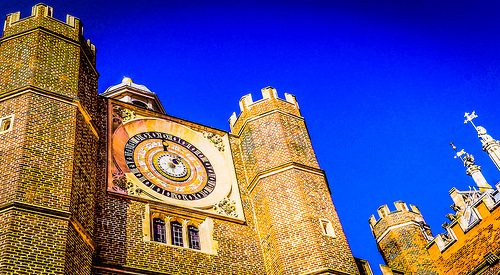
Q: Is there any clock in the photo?
A: Yes, there is a clock.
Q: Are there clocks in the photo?
A: Yes, there is a clock.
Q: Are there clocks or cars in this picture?
A: Yes, there is a clock.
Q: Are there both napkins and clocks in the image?
A: No, there is a clock but no napkins.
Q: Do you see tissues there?
A: No, there are no tissues.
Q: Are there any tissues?
A: No, there are no tissues.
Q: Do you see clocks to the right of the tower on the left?
A: Yes, there is a clock to the right of the tower.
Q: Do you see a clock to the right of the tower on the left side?
A: Yes, there is a clock to the right of the tower.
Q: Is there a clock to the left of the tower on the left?
A: No, the clock is to the right of the tower.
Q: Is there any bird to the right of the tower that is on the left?
A: No, there is a clock to the right of the tower.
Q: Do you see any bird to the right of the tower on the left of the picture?
A: No, there is a clock to the right of the tower.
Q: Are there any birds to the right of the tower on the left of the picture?
A: No, there is a clock to the right of the tower.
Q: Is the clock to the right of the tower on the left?
A: Yes, the clock is to the right of the tower.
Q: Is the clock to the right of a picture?
A: No, the clock is to the right of the tower.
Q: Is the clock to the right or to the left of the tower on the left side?
A: The clock is to the right of the tower.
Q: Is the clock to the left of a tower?
A: Yes, the clock is to the left of a tower.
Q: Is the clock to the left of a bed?
A: No, the clock is to the left of a tower.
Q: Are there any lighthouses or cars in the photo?
A: No, there are no cars or lighthouses.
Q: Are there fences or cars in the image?
A: No, there are no cars or fences.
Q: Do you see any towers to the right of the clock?
A: Yes, there is a tower to the right of the clock.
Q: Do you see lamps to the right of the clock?
A: No, there is a tower to the right of the clock.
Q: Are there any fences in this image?
A: No, there are no fences.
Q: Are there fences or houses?
A: No, there are no fences or houses.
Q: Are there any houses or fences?
A: No, there are no fences or houses.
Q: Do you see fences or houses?
A: No, there are no fences or houses.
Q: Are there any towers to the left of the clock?
A: Yes, there is a tower to the left of the clock.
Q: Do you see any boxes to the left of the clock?
A: No, there is a tower to the left of the clock.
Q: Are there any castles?
A: Yes, there is a castle.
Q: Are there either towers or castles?
A: Yes, there is a castle.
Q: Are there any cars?
A: No, there are no cars.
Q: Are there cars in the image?
A: No, there are no cars.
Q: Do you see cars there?
A: No, there are no cars.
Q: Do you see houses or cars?
A: No, there are no cars or houses.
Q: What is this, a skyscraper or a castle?
A: This is a castle.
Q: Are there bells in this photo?
A: No, there are no bells.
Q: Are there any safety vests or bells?
A: No, there are no bells or safety vests.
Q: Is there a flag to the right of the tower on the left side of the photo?
A: Yes, there are flags to the right of the tower.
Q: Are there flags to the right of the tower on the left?
A: Yes, there are flags to the right of the tower.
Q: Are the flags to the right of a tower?
A: Yes, the flags are to the right of a tower.